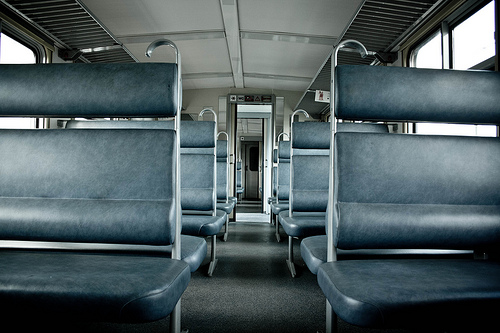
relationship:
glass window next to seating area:
[404, 8, 500, 133] [272, 35, 497, 319]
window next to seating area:
[0, 26, 48, 132] [0, 37, 244, 322]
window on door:
[8, 26, 65, 195] [242, 136, 266, 200]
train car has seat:
[1, 0, 498, 331] [4, 37, 184, 333]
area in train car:
[6, 141, 498, 312] [1, 0, 498, 331]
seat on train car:
[311, 51, 494, 328] [1, 0, 498, 331]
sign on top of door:
[227, 89, 274, 104] [227, 103, 271, 221]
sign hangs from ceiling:
[314, 89, 329, 104] [2, 0, 498, 110]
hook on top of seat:
[146, 31, 183, 66] [336, 63, 498, 326]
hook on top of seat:
[323, 32, 373, 64] [4, 67, 191, 315]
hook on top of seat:
[198, 100, 221, 121] [295, 123, 331, 254]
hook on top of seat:
[289, 103, 313, 123] [178, 122, 221, 272]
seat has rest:
[322, 37, 493, 328] [9, 63, 179, 124]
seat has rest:
[4, 37, 184, 333] [340, 66, 495, 133]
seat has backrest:
[4, 67, 191, 315] [3, 62, 178, 246]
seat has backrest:
[311, 51, 494, 328] [338, 128, 496, 249]